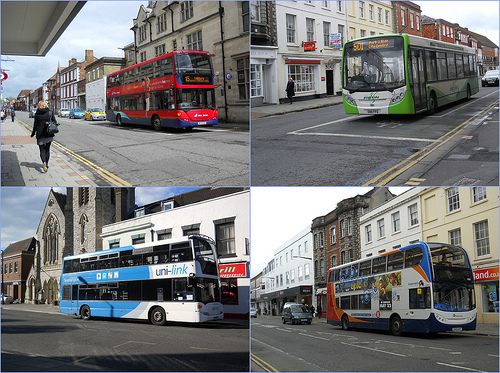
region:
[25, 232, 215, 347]
blue bus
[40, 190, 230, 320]
blue bus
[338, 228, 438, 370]
the bus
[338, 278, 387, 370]
the water is blue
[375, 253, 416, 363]
the water is blue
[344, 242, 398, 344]
the water is blue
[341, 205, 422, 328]
the water is blue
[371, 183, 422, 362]
the water is blue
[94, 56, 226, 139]
red double-decker bus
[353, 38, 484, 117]
green and white bus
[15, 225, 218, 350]
blue and white double-decker bus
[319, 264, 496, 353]
red, white, and blue double-decker bus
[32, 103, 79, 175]
woman walks on sidewalk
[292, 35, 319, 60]
red sign on building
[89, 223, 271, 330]
white building behind blue bus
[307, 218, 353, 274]
brick building behind red, white, and blue bus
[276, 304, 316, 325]
blue van behind bus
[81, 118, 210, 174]
light grey road near bus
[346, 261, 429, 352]
a bus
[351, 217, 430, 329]
a bus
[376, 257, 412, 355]
a bus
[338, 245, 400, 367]
a bus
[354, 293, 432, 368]
a bus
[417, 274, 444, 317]
edge of a bus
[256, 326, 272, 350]
part of a line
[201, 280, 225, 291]
part of a window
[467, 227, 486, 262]
part of a window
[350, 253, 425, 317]
side of ab bus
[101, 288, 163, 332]
side of a bus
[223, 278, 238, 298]
part of a stoore